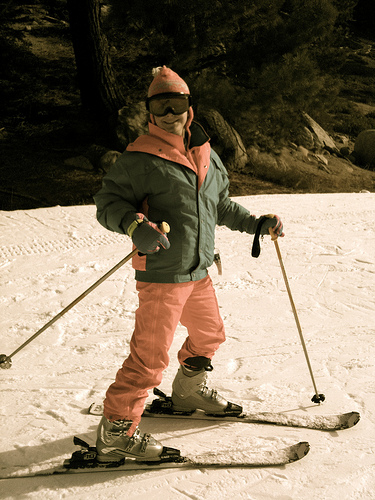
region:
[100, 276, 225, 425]
a pair of pink snow pants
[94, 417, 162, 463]
a silver snow ski boot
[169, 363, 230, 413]
a silver snow ski boot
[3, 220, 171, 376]
a black and silver ski pole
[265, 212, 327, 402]
a black and silver ski pole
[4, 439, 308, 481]
a snow covered black ski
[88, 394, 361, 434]
a snow covered black ski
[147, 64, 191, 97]
a pink ski hat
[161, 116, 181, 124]
a smile on a face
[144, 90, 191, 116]
a pair of black ski goggles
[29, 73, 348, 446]
skier standing in the snow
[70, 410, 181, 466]
ski boot on person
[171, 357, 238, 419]
ski boot on person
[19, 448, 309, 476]
long ski on woman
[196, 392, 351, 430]
long ski on woman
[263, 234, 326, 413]
ski pole in woman's hand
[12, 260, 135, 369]
ski pole in woman's hand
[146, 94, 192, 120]
goggles on woman's face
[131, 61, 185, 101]
hat on woman's head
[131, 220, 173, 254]
glove on woman's hand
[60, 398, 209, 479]
brown ski boots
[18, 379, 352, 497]
skis on the snow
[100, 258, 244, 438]
orange snow pants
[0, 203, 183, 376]
a long metal ski pole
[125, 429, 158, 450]
straps on a ski boot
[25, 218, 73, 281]
tracks in the snow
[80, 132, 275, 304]
a ski jacket on a skier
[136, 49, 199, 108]
a winter hat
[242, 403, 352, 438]
powdered snow on a ski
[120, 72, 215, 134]
black ski goggles on a skier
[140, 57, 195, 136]
peach colored kniw hat with goggles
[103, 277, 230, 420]
peach snow pants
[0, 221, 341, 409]
ski poles for balance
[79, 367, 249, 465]
silver colored ski boots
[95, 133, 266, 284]
olive green parka with peach trim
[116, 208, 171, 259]
olive and peach accent ski gloves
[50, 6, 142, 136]
a tree trunk with rough bark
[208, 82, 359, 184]
boulders and rocks off trail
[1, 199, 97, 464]
many kinds of tracks in the snow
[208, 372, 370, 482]
ski tips are turned up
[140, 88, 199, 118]
Ski goggles.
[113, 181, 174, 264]
Ski glove.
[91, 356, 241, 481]
Ski boots.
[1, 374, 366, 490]
Ski's attached to ski boots.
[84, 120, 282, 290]
A green and pink winter jacket.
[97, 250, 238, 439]
Pink winter pants.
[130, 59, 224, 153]
Pink winter hat.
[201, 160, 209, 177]
Button on coat collar.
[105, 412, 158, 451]
Clasp on ski shoe.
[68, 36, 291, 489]
Man skiing and smiling.